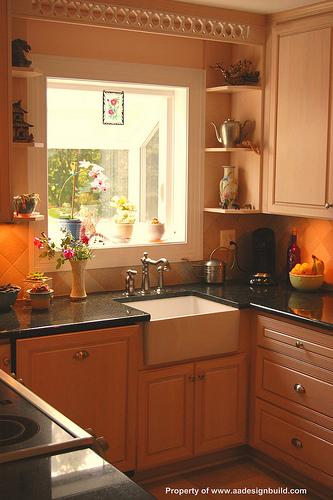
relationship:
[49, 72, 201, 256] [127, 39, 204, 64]
window in wall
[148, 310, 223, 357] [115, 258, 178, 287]
sink with faucet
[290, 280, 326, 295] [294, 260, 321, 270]
bowl of fruit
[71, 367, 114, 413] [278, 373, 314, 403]
cabinets with knobs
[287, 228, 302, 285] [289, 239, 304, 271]
wine bottle of wine bottle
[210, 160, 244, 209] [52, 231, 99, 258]
vase of flowers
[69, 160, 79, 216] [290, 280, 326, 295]
cactus in bowl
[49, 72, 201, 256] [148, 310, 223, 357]
window over sink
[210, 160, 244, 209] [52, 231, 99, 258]
vase has flowers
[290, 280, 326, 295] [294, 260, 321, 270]
bowl has fruit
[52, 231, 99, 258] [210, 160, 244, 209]
flowers in vase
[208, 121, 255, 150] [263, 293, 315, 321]
teapot on countertop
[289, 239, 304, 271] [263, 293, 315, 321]
wine bottle on countertop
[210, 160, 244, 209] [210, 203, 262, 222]
vase on shelf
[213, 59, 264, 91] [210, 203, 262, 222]
figurine on shelf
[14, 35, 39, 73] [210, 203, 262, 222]
figurine on shelf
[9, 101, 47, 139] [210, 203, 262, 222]
figurine on shelf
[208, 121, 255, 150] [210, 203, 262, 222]
teapot on shelf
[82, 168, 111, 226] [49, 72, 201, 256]
orchid in window